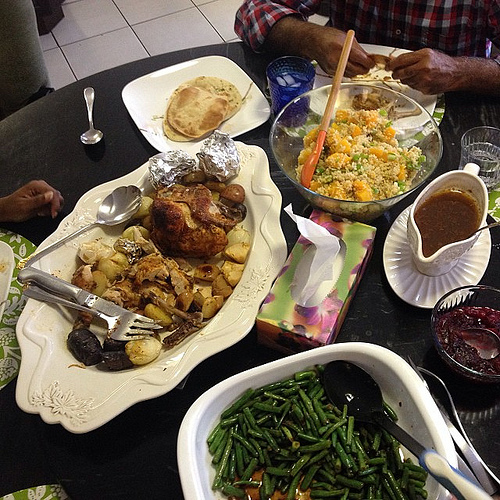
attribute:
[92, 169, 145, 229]
spoon — gray 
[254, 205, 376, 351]
tissue — white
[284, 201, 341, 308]
tissue piece — white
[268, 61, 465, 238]
bowl — white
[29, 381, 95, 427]
design — beautiful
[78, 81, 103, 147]
spoon — gray , metal 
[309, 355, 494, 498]
spoon — gray, black, large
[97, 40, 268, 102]
plate — white 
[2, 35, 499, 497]
table — black 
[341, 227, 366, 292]
napkin box — multicolored  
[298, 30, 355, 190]
tablespoon — orange , wooden 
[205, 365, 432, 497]
green beans — green 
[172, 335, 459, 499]
white pot — white 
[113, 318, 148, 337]
fork — gray, metal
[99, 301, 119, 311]
knife — metal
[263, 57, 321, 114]
glass — blue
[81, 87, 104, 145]
spoon — small, silver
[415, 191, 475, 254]
gravy — brown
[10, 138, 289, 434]
plate — white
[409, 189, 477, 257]
gravy — brown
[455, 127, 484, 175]
glass — clear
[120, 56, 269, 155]
platter — small